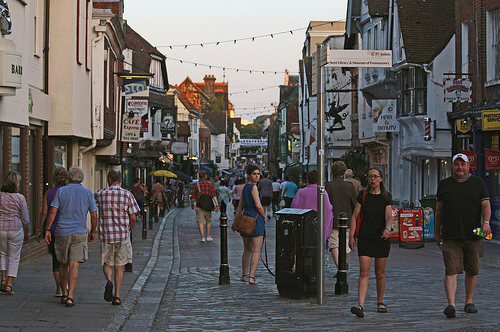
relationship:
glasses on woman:
[361, 169, 393, 186] [327, 169, 408, 289]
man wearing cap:
[433, 148, 493, 316] [452, 152, 470, 161]